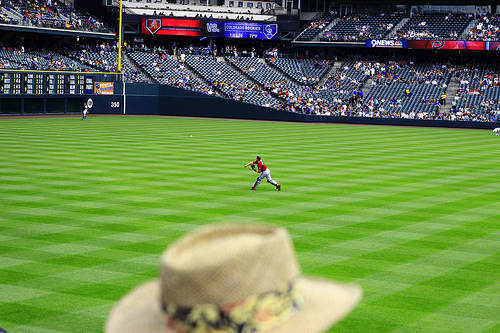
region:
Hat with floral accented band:
[96, 210, 375, 329]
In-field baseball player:
[232, 145, 294, 198]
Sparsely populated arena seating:
[6, 46, 498, 142]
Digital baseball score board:
[1, 71, 111, 99]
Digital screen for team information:
[130, 10, 289, 45]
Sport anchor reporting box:
[101, 0, 313, 22]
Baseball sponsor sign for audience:
[87, 75, 128, 99]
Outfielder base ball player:
[78, 100, 95, 120]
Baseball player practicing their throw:
[129, 118, 309, 199]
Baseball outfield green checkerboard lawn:
[336, 135, 485, 272]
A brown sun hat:
[103, 218, 366, 331]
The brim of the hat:
[299, 280, 339, 317]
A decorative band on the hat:
[176, 306, 260, 331]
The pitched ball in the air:
[188, 133, 195, 138]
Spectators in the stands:
[286, 98, 339, 114]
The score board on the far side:
[3, 70, 73, 92]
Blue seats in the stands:
[258, 68, 275, 80]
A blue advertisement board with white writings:
[368, 39, 395, 47]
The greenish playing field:
[44, 157, 226, 214]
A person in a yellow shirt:
[438, 91, 448, 103]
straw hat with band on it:
[106, 215, 373, 332]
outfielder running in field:
[242, 153, 282, 196]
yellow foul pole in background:
[110, 3, 128, 77]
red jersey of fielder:
[253, 161, 265, 168]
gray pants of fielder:
[255, 170, 277, 182]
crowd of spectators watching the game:
[8, 3, 493, 104]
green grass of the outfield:
[3, 113, 491, 328]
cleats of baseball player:
[252, 186, 282, 196]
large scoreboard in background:
[141, 8, 275, 50]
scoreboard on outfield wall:
[2, 70, 95, 98]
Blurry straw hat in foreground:
[103, 218, 362, 332]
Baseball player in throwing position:
[243, 155, 278, 189]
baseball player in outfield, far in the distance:
[81, 103, 88, 118]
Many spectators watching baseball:
[0, 0, 499, 122]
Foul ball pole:
[118, 0, 122, 72]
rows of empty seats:
[369, 85, 439, 98]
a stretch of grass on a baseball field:
[0, 115, 499, 330]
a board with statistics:
[0, 70, 122, 96]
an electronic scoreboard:
[141, 15, 278, 39]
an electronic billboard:
[366, 38, 499, 49]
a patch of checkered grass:
[0, 151, 231, 241]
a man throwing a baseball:
[186, 125, 288, 192]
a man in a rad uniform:
[242, 153, 290, 190]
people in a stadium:
[187, 43, 497, 122]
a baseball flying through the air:
[186, 130, 195, 138]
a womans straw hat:
[96, 212, 366, 332]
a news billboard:
[368, 38, 405, 46]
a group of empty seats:
[268, 65, 281, 79]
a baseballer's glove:
[250, 163, 255, 170]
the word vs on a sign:
[202, 20, 222, 33]